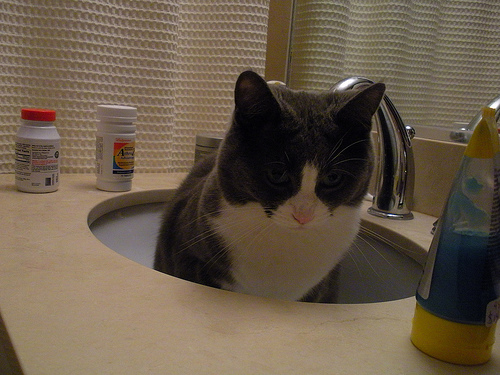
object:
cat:
[152, 70, 387, 304]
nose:
[292, 199, 317, 227]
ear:
[234, 70, 281, 128]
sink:
[87, 189, 428, 305]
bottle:
[93, 101, 137, 192]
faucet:
[326, 76, 417, 220]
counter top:
[0, 177, 500, 374]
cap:
[21, 108, 56, 122]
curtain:
[2, 2, 274, 175]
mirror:
[282, 3, 499, 146]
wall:
[265, 1, 466, 219]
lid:
[410, 299, 498, 365]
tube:
[414, 95, 499, 330]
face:
[227, 131, 369, 226]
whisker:
[181, 205, 420, 273]